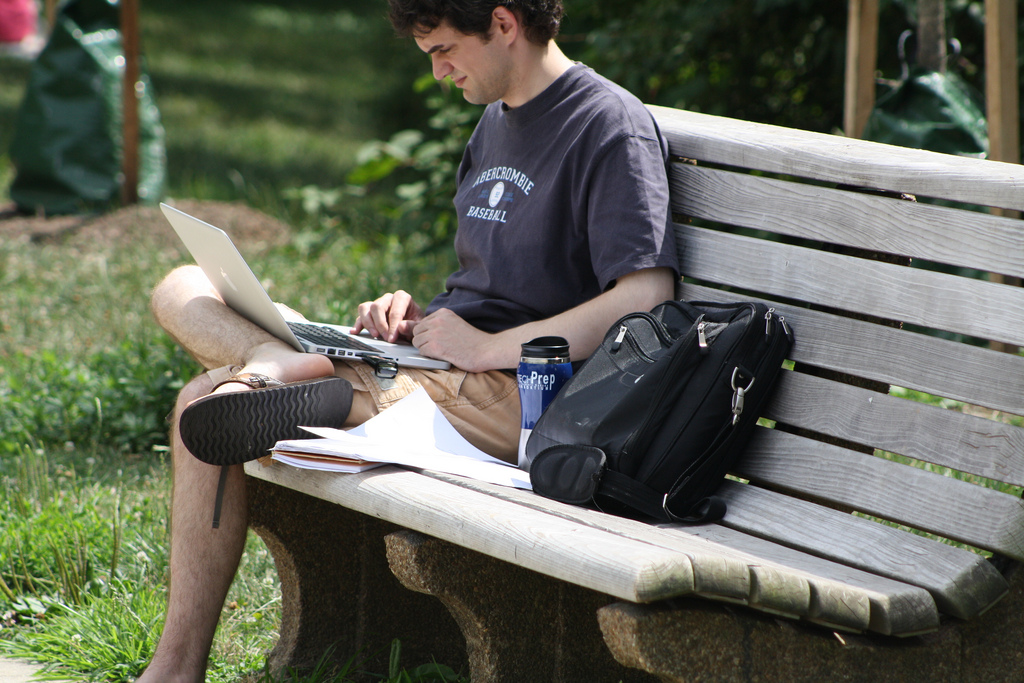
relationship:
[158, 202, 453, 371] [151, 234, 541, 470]
lap on lap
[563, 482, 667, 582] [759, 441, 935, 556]
wood on bench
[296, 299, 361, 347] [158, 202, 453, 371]
keyboard on a lap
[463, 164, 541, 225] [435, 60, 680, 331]
design on man's t-shirt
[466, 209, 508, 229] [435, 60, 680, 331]
name on man's t-shirt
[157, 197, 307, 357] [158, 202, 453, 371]
lid of lap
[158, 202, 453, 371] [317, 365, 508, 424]
lap on man's lap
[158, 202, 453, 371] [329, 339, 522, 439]
lap on man's lap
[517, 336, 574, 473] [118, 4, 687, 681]
coffee mug next to man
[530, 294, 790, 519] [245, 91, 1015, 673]
bag on bench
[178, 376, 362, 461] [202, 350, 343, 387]
sandal on foot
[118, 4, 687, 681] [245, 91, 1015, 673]
man sitting on bench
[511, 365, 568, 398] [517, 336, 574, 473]
lettering on coffee mug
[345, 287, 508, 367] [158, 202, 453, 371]
man's hands resting on lap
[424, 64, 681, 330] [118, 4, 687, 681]
man's t-shirt worn by man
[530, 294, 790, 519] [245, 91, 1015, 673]
bag in bench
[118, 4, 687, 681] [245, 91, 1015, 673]
man sitting in bench